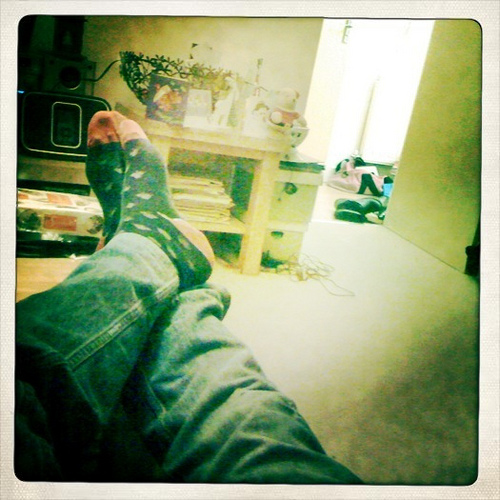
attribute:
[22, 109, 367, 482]
legs — folded, wearing jeans, crossed, extended, in jeans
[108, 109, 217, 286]
feet — wearing socks, black, pink, with socks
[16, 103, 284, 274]
stand — white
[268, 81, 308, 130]
teddy bear — on the wall, white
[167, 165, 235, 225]
sheets — stacked, piled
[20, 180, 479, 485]
floor — bright, off white, white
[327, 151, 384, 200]
bag — pink, black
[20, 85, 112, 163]
stereo speaker — black, electronic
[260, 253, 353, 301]
cords — tangled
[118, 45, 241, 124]
basket — black, open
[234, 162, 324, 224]
boxes — white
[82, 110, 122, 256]
right sock — on right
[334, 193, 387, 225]
shoes — disarranged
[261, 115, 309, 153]
bowl — white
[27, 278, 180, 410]
seam — inside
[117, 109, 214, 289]
sock — on left